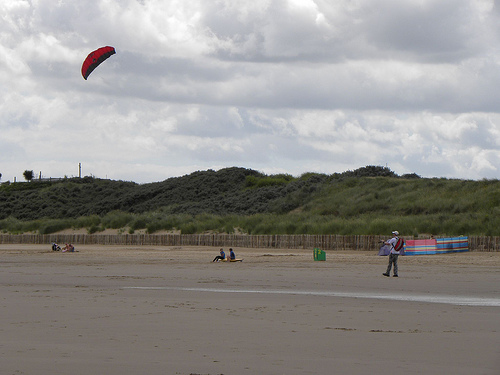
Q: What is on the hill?
A: Lush greenery.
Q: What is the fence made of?
A: Wood.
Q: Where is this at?
A: A beach.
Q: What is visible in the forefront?
A: Sand.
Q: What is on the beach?
A: People walking.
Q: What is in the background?
A: Hills.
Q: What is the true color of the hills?
A: Green.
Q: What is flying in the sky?
A: Kite.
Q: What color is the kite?
A: Red.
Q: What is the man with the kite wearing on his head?
A: Hat.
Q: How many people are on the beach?
A: Seven.